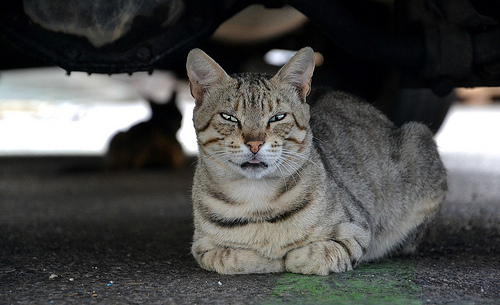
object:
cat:
[106, 91, 183, 168]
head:
[185, 47, 315, 178]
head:
[149, 91, 183, 129]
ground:
[0, 118, 500, 305]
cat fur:
[185, 44, 450, 273]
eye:
[220, 113, 239, 123]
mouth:
[238, 161, 268, 173]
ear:
[271, 45, 316, 103]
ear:
[187, 48, 233, 97]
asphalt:
[0, 183, 499, 305]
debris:
[35, 264, 118, 291]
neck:
[196, 146, 316, 206]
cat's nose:
[245, 140, 263, 153]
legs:
[192, 225, 371, 276]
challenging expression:
[208, 102, 298, 177]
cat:
[186, 47, 446, 275]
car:
[0, 0, 500, 134]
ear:
[168, 91, 177, 104]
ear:
[148, 97, 158, 108]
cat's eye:
[268, 112, 286, 122]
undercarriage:
[20, 0, 427, 77]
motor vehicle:
[0, 0, 499, 138]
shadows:
[424, 215, 500, 256]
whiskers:
[268, 149, 323, 193]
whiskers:
[190, 151, 242, 174]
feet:
[227, 240, 346, 276]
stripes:
[192, 180, 310, 237]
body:
[184, 47, 447, 275]